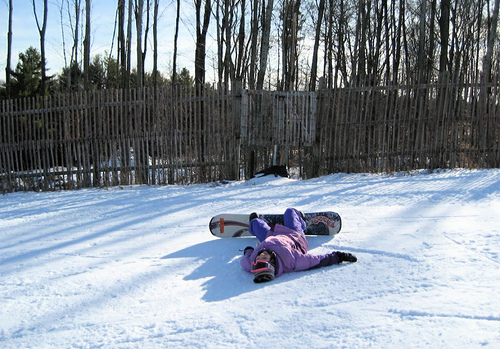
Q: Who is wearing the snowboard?
A: The woman.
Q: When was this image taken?
A: Daytime.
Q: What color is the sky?
A: Blue.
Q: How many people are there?
A: One.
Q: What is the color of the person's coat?
A: Purple.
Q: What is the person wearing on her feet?
A: Snowboard.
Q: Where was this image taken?
A: Someone's huge backyard.